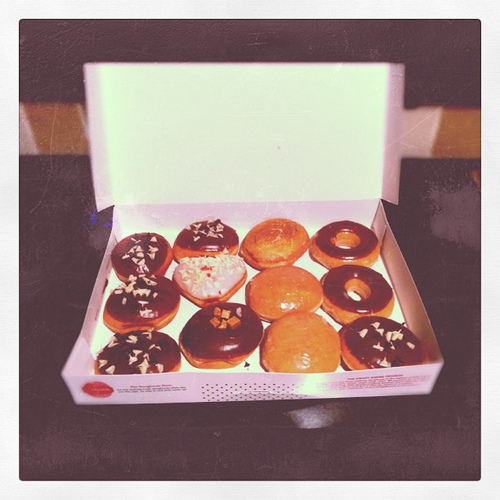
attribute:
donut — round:
[174, 217, 239, 257]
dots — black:
[202, 381, 299, 402]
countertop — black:
[25, 152, 478, 482]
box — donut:
[57, 53, 448, 413]